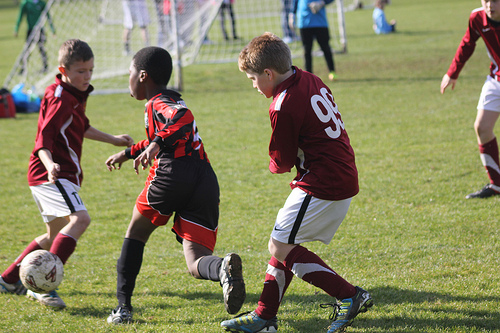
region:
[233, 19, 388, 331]
This is a boy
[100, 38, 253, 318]
This is a boy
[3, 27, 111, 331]
This is a boy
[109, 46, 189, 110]
Head of a boy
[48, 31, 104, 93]
Head of a boy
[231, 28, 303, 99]
Head of a boy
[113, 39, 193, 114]
Head of a boy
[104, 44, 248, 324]
this boy is dark skinned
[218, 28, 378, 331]
this boy is caucasian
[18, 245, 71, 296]
the soccer ball is bouncing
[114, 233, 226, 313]
the boy's socks are black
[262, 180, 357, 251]
the soccer shorts are white with a black stripe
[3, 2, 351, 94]
the goal net is white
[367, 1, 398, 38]
a child in a blue shirt is sitting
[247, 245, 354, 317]
the socks are red with a white stripe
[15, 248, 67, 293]
the soccer ball is worn and dirty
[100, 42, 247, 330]
the boy in the middle is running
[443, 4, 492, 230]
Person standing in a field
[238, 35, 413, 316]
Person standing in a field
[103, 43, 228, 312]
Person standing in a field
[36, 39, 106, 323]
Person standing in a field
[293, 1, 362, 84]
Person standing in a field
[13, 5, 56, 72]
Person standing in a field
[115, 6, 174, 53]
Person standing in a field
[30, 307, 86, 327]
Patch of green grass in the field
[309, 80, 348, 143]
number 99 on the back of a red shirt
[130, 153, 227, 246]
boy's red and black shorts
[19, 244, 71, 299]
soccer ball above the ground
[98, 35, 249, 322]
soccer player with black hair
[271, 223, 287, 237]
nike emblem on white shorts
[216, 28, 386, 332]
boy wearing number 99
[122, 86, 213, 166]
red and black jersey top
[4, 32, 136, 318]
boy closest to the ball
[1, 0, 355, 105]
net on the field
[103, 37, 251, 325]
boy on an opposing team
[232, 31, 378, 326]
boy wearing long socks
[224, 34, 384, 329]
boy with number 99 on his jersey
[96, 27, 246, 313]
boy wearing red and black shorts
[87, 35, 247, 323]
boy wearing long black socks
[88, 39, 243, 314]
boy wearing red and black shirt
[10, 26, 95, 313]
boy kicking the soccer ball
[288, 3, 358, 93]
man wearing black pants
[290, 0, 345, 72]
man wearing light blue shirt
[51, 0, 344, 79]
soccer goalie net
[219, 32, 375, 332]
Young boy in red and white uniform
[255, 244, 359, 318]
Red socks with white "swoosh" worn by soccer player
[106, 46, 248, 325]
Black boy in red and black uniform running towards soccer ball